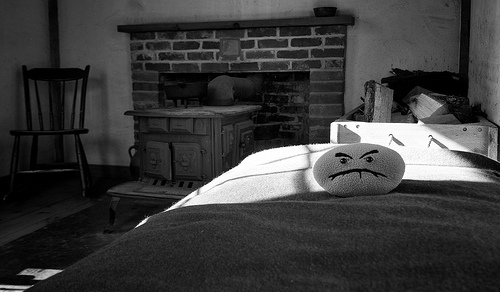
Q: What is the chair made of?
A: Wood.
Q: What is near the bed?
A: Fireplace.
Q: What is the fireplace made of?
A: Brick.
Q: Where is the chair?
A: In the corner of the room.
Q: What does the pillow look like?
A: A human face.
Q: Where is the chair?
A: In the corner.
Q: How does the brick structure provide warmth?
A: Fire.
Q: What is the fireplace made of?
A: Bricks.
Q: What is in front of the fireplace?
A: Stove.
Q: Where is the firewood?
A: Behind the bed.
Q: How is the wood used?
A: Burn.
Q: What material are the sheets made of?
A: Wool.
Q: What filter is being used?
A: Black and white.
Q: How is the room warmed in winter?
A: Wood stove.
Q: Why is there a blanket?
A: Cover bed.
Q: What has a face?
A: Pillow.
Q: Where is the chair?
A: Left rear.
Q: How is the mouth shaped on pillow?
A: Frown.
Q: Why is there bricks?
A: Frame the fireplace.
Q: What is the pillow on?
A: Bed.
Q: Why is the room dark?
A: The light is turned off.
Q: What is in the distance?
A: A fireplace.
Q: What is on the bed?
A: A pillow.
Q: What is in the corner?
A: A chair.